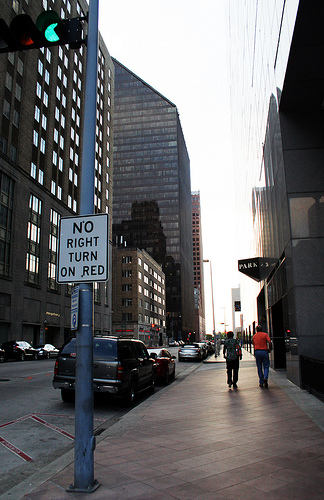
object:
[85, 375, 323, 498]
tiles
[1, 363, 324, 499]
sidewalk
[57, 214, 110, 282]
sign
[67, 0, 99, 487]
pole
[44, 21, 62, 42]
light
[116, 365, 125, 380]
light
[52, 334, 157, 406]
car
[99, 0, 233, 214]
sky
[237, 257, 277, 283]
sign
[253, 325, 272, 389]
man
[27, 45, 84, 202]
windows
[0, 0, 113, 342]
building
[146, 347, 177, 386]
car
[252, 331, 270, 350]
shirt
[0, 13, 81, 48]
signal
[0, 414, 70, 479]
stripes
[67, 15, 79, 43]
bolts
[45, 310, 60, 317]
writing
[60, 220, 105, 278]
letters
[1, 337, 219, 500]
road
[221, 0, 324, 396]
building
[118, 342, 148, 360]
window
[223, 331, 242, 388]
man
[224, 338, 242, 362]
shirt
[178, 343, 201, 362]
car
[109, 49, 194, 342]
sky scraper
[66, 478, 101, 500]
bolts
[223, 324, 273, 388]
couple